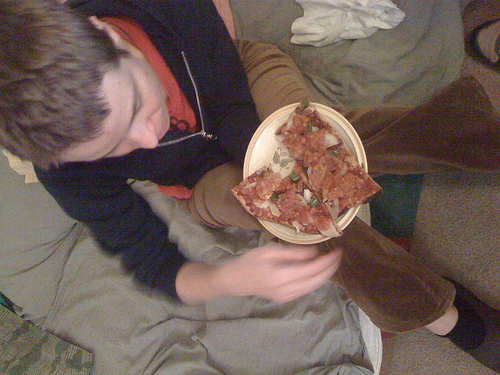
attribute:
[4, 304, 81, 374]
cushion — green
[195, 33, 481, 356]
pants — brown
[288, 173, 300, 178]
topping — green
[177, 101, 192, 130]
shirt — red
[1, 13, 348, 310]
jacket — blue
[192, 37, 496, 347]
trousers — brown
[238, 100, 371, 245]
plate — edge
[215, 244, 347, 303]
hand — motion blurred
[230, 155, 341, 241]
pizza — one slice, meat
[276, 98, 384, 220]
pizza — meat, one slice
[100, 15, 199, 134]
tshirt — red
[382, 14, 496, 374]
rug — brown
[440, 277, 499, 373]
loafer — Black 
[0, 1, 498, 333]
white male — young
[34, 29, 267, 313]
sweater — black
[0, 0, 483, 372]
bed — messy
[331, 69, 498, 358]
pants — brown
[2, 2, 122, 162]
hair — brown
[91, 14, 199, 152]
shirt — orange